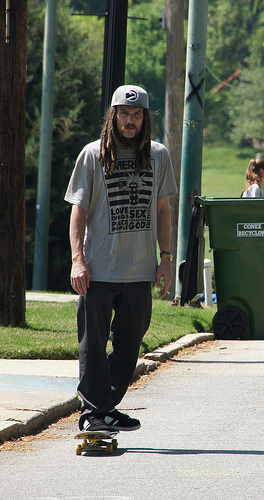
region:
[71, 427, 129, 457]
a yellow and black skateboard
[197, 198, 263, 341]
a green trash can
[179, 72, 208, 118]
a black X painted on light pole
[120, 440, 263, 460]
shadow of skateboarder on ground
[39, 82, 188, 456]
a man skateboarding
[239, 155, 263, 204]
a woman with brown hair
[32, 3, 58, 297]
a silver metal light pole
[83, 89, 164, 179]
a man with dreadlocks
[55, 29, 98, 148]
trees with green leaves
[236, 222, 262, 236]
recycle sign on trash can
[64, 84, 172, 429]
a man riding a skateboard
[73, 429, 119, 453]
a skateboard with yellow wheels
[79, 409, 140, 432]
black and white shoes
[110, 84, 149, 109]
a grey cap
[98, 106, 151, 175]
brown dreadlocks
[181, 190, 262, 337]
a large green recycling bin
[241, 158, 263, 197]
a woman in the background with a ponytail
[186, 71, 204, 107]
a black X painted on a pole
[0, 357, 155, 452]
sidewalk near the street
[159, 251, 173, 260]
a wristwatch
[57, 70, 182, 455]
a man skate boarding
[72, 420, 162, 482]
the skateboard of the man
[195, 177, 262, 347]
the garbage can for recylcing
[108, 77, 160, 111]
the atlanta hawks hat of the guy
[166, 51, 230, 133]
the pole with the X on it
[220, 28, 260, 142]
the trees in the back ground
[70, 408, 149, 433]
the shoes on the guy on skateboard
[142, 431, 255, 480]
the shadow that is casted by the skate boarder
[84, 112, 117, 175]
the dreads of the skate boarder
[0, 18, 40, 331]
the tree in the front yard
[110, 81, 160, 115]
gray hat with black design on front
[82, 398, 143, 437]
black and white tennis shoes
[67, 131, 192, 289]
gray shirt with black writing on front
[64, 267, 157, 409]
mens black athletic pants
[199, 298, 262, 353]
black plastic wheel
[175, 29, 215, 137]
graffiti with black paint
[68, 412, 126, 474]
wooden skateboard with yellow wheels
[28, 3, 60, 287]
metal pole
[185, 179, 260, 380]
green and black recycling bin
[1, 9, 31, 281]
wooden power pole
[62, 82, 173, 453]
Man skateboarding on street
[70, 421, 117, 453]
Skateboard being used by a man on the street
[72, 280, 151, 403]
Dark pants on a male skateboarder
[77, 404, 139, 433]
Black and white shoes on skateboarder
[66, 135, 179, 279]
Gray shirt with black lettering on skateboarder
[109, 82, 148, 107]
Gray hat with white design worn by skateboarder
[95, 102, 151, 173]
Dreadlocks on male skateboarder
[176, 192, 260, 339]
Green trash can on street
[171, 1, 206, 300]
Green pole with black "x"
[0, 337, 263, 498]
Gray street used by skateboarder